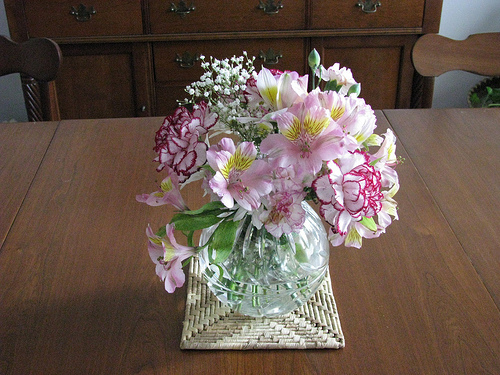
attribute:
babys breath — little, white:
[167, 46, 269, 144]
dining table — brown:
[4, 103, 497, 373]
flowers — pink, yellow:
[251, 91, 364, 199]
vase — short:
[197, 201, 331, 321]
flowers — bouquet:
[145, 57, 436, 285]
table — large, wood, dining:
[8, 127, 151, 369]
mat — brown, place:
[177, 315, 344, 350]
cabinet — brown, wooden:
[2, 0, 447, 119]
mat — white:
[175, 249, 347, 367]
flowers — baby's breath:
[193, 49, 253, 107]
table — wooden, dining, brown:
[1, 101, 496, 373]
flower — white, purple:
[149, 100, 218, 178]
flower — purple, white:
[243, 70, 296, 102]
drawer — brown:
[349, 0, 409, 29]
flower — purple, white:
[313, 150, 383, 232]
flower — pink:
[133, 210, 223, 290]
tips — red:
[338, 160, 387, 209]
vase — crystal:
[177, 191, 347, 360]